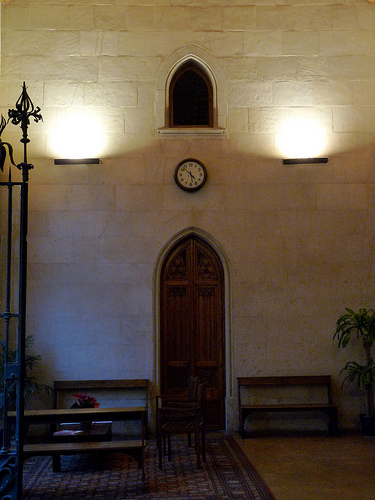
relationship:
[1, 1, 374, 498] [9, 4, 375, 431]
building has walls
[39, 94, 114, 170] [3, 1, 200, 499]
light on left side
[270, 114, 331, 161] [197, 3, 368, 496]
light on right side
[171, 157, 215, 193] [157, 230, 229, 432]
clock above door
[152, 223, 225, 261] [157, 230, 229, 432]
arch of door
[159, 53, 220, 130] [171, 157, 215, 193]
window above clock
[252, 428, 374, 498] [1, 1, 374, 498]
floor of building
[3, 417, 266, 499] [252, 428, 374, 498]
carpet on floor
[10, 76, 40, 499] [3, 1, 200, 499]
stick on left side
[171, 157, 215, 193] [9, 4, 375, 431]
clock on walls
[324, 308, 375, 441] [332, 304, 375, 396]
potted plant with leaves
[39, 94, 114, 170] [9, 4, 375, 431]
light on walls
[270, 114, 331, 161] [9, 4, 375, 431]
light on walls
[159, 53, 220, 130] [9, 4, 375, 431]
window on walls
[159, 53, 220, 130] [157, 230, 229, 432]
window above door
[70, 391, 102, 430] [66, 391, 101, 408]
plant with flowers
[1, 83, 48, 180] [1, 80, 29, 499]
design on fencing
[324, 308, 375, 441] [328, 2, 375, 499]
potted plant in corner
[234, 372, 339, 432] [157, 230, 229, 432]
bench next to door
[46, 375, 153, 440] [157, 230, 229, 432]
bench next to door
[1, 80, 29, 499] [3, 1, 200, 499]
fencing on left side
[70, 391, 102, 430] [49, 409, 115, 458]
plant on table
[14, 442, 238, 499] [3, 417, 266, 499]
designs on carpet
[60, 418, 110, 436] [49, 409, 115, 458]
magazines on table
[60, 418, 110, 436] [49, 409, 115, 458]
magazines laying on table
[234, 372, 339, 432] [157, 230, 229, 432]
bench to left of door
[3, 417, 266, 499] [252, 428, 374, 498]
carpet laying on floor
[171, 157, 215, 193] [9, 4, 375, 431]
clock hanging on walls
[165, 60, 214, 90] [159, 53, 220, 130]
arched top of window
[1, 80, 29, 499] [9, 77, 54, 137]
fencing with sharp points